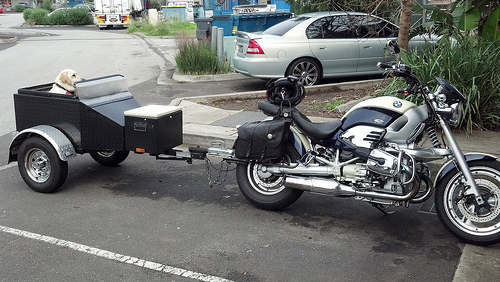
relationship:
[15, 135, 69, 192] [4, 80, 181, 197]
wheel on trailer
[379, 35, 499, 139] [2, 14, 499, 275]
grass on ground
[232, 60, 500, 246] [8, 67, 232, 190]
motorcycle pulling trailer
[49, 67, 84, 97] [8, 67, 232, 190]
dog in trailer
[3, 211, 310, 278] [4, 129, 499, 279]
line painted on road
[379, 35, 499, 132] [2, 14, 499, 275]
grass on ground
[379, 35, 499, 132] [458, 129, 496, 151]
grass on ground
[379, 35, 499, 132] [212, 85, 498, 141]
grass on ground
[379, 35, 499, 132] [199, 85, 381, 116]
grass on ground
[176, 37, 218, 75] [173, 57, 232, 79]
grass on ground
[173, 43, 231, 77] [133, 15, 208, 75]
grass on ground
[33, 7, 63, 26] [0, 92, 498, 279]
grass on ground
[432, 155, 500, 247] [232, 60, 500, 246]
wheel on motorcycle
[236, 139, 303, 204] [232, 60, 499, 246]
wheel on motorcycle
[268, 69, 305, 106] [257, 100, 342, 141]
helmet on black seat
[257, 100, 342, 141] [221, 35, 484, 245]
black seat on motorcycle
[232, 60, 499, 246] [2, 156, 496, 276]
motorcycle on street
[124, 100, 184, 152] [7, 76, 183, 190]
cooler on attachment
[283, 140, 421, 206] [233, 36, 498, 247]
silver engine on motorcycle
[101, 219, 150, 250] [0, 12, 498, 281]
patch on road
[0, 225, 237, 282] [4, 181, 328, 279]
line on street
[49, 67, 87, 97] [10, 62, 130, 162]
dog sitting in cart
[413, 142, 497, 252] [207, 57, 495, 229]
wheel on motorcycle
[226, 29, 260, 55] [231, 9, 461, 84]
headlights on car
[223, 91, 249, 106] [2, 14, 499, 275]
dirt patch on ground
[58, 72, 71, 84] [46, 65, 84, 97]
brown ear on dog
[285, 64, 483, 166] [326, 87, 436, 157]
emblem on tank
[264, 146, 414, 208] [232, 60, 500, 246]
exhaust pipes on motorcycle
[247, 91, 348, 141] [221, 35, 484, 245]
black seat mounted on motorcycle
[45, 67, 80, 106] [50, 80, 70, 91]
lab wearing collar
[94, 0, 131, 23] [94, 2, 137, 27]
back end belonging to trailer